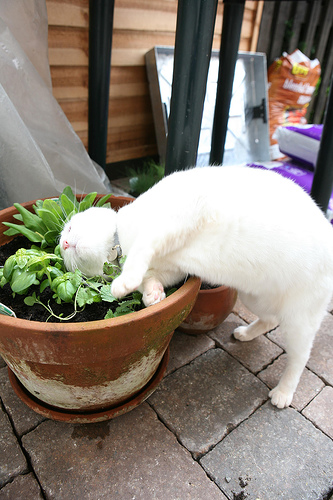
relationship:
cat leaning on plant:
[39, 160, 333, 410] [1, 186, 208, 408]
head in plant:
[48, 198, 129, 281] [0, 183, 156, 322]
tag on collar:
[102, 246, 126, 269] [100, 215, 130, 270]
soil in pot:
[1, 225, 192, 324] [1, 186, 205, 429]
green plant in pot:
[0, 186, 178, 320] [1, 186, 205, 429]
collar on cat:
[102, 210, 140, 268] [39, 160, 333, 410]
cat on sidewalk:
[39, 160, 333, 410] [2, 171, 322, 499]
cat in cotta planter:
[39, 160, 333, 410] [0, 184, 191, 321]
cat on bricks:
[39, 160, 333, 410] [168, 349, 313, 456]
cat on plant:
[39, 160, 333, 410] [15, 258, 136, 316]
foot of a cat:
[261, 377, 301, 421] [43, 167, 301, 407]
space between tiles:
[201, 407, 245, 442] [176, 383, 306, 476]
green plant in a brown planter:
[18, 225, 59, 269] [19, 278, 157, 399]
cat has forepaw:
[60, 164, 311, 414] [138, 280, 168, 308]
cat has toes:
[60, 164, 311, 414] [145, 289, 160, 301]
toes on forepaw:
[145, 289, 160, 301] [138, 280, 168, 308]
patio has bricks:
[9, 125, 322, 484] [11, 311, 310, 496]